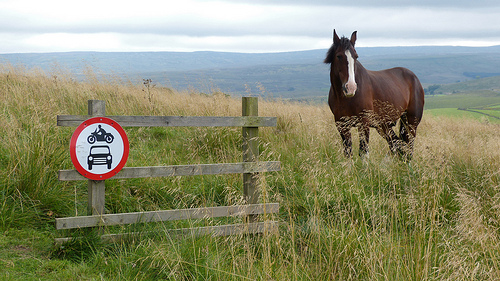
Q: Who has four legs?
A: A horse.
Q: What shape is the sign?
A: Round.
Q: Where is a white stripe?
A: On horse's face.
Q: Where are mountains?
A: In the far distance.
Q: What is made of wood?
A: A small fence.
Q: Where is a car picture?
A: On sign.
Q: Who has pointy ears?
A: On horse's head.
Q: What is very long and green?
A: Grass.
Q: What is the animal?
A: Horse.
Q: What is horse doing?
A: Standing.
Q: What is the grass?
A: Tall.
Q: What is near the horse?
A: Fence.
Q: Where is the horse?
A: Grass.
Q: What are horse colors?
A: Brown and white.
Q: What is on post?
A: Sign.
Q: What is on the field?
A: Grass.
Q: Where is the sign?
A: On wood.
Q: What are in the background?
A: Rolling hills.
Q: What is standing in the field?
A: A horse.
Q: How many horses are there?
A: One.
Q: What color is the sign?
A: Red and white.